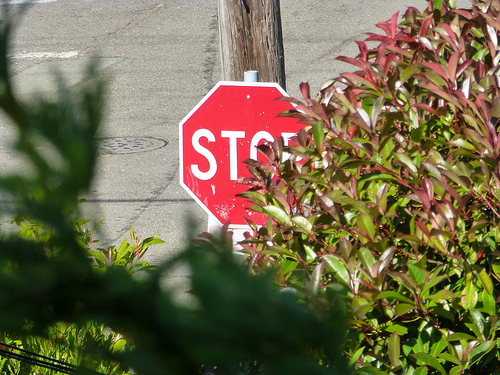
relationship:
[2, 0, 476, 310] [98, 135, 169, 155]
road has manhole cover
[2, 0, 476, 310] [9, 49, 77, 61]
road has line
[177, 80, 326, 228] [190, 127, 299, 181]
sign saying stop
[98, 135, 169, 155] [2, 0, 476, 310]
manhole cover on top of road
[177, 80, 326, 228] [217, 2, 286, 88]
sign attached to pole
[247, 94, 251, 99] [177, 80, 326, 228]
bolt holding sign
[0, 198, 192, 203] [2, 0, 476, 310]
shadow on top of road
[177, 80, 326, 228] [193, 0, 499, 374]
sign behind bush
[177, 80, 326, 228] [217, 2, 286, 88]
sign in front of pole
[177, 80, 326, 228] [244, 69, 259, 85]
sign has pole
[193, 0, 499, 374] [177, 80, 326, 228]
bush covering sign